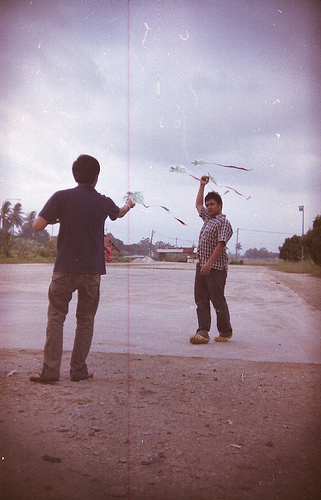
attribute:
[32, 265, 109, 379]
pants — pair, grey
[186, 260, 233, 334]
jeans — pair, blue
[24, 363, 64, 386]
shoe — man's, sandal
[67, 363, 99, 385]
shoe — sandal, man's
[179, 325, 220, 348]
shoe — man's, sandal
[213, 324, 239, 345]
shoe — sandal, man's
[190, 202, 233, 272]
shirt — checkered, white, black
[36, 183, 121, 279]
shirt — blue, dark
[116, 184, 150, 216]
kite — white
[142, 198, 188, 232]
tail — red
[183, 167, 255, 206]
tail — red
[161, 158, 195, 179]
kite — white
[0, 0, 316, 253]
sky — blue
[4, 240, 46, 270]
leaves — green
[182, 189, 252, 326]
man — holding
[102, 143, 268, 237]
kites — holding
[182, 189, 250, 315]
man — holding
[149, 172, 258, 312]
man — holding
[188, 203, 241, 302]
man — holding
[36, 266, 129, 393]
pants — brown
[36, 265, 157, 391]
pants — brown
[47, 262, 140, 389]
pants — brown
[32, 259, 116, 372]
pants — brown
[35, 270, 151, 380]
pants — brown